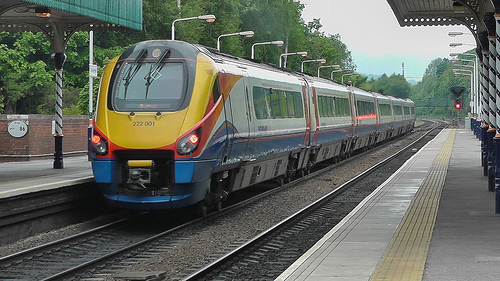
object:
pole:
[23, 19, 90, 168]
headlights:
[90, 134, 109, 155]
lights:
[217, 31, 255, 51]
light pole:
[301, 59, 327, 73]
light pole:
[251, 40, 284, 59]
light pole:
[171, 15, 216, 41]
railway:
[0, 119, 463, 281]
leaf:
[34, 65, 45, 77]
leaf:
[22, 32, 32, 46]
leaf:
[71, 46, 82, 64]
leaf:
[324, 49, 341, 59]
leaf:
[185, 2, 199, 14]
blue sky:
[350, 54, 423, 76]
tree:
[200, 0, 249, 55]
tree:
[144, 0, 212, 39]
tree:
[245, 0, 305, 62]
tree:
[292, 10, 323, 67]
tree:
[316, 30, 356, 77]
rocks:
[195, 202, 267, 260]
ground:
[367, 170, 401, 205]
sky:
[297, 3, 467, 79]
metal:
[188, 117, 428, 274]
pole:
[316, 62, 340, 77]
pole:
[330, 67, 350, 81]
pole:
[81, 29, 98, 115]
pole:
[279, 51, 308, 67]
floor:
[428, 182, 480, 224]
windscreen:
[111, 58, 188, 112]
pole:
[455, 42, 495, 136]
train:
[89, 39, 416, 218]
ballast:
[268, 196, 285, 218]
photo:
[1, 0, 483, 275]